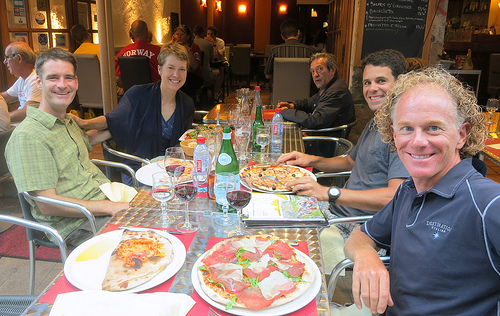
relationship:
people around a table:
[20, 39, 491, 312] [16, 103, 330, 315]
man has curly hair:
[330, 63, 500, 315] [371, 63, 491, 159]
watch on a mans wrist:
[328, 185, 341, 204] [324, 186, 342, 202]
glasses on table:
[152, 88, 272, 243] [16, 103, 330, 315]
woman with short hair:
[64, 40, 196, 188] [157, 41, 191, 73]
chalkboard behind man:
[357, 0, 438, 69] [277, 51, 358, 158]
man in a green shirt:
[5, 47, 139, 247] [7, 103, 111, 245]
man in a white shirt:
[0, 41, 44, 123] [4, 72, 41, 115]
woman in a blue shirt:
[64, 40, 196, 188] [105, 81, 196, 191]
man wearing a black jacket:
[277, 51, 358, 158] [287, 77, 357, 157]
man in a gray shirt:
[275, 50, 410, 258] [332, 111, 411, 230]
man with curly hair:
[330, 63, 500, 315] [371, 63, 491, 159]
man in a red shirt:
[114, 19, 162, 80] [113, 40, 161, 86]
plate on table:
[65, 226, 188, 292] [39, 97, 339, 309]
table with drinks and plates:
[39, 97, 339, 309] [65, 227, 323, 316]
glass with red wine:
[226, 175, 253, 232] [227, 190, 252, 207]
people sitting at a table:
[20, 39, 491, 312] [16, 103, 330, 315]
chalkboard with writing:
[357, 0, 438, 69] [364, 1, 428, 34]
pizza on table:
[238, 162, 311, 191] [16, 103, 330, 315]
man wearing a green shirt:
[5, 47, 139, 247] [7, 103, 111, 245]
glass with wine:
[226, 175, 253, 232] [227, 190, 252, 207]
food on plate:
[206, 236, 306, 305] [193, 235, 322, 315]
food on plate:
[79, 231, 174, 287] [65, 226, 188, 292]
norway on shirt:
[123, 48, 155, 60] [113, 40, 161, 86]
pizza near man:
[238, 162, 311, 191] [275, 50, 410, 258]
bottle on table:
[213, 125, 241, 214] [16, 103, 330, 315]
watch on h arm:
[328, 185, 341, 204] [291, 140, 411, 208]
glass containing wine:
[226, 175, 253, 232] [227, 190, 252, 207]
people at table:
[20, 39, 491, 312] [39, 97, 339, 309]